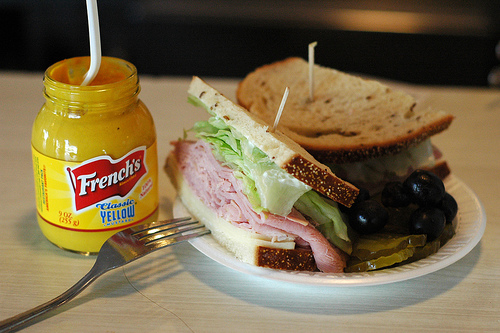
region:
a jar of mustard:
[25, 63, 160, 253]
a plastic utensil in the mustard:
[78, 4, 108, 86]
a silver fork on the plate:
[12, 221, 203, 331]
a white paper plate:
[176, 198, 481, 283]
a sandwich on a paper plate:
[166, 36, 479, 276]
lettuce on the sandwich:
[214, 118, 302, 191]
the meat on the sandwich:
[174, 144, 248, 208]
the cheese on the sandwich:
[195, 200, 220, 222]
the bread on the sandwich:
[248, 51, 442, 149]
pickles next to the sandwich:
[363, 227, 421, 272]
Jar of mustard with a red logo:
[33, 52, 163, 239]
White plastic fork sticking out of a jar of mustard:
[78, 0, 109, 92]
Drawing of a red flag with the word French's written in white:
[59, 140, 153, 211]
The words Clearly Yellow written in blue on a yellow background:
[90, 193, 137, 225]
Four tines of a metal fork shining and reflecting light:
[121, 209, 205, 248]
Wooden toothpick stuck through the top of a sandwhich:
[298, 30, 323, 105]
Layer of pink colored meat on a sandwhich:
[187, 140, 250, 221]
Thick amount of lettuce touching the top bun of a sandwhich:
[208, 128, 300, 203]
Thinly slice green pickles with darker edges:
[352, 230, 424, 263]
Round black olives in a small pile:
[377, 168, 459, 229]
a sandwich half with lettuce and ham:
[178, 75, 353, 285]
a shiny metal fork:
[1, 223, 204, 331]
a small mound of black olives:
[355, 173, 452, 231]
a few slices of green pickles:
[346, 231, 435, 273]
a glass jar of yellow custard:
[32, 57, 163, 253]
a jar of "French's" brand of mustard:
[32, 59, 163, 249]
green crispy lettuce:
[187, 109, 354, 259]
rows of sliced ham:
[166, 132, 332, 259]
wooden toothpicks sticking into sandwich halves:
[262, 39, 322, 126]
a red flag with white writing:
[69, 152, 149, 206]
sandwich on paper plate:
[171, 55, 485, 283]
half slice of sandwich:
[164, 76, 351, 266]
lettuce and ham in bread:
[159, 81, 349, 270]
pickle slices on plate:
[347, 232, 438, 273]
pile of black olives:
[356, 170, 459, 237]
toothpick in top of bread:
[271, 87, 292, 132]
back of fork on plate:
[3, 217, 208, 329]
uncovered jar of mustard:
[33, 57, 160, 257]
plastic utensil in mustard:
[84, 1, 101, 84]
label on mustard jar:
[32, 134, 158, 231]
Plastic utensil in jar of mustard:
[28, 0, 163, 258]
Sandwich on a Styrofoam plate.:
[163, 32, 457, 275]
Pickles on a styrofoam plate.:
[348, 230, 447, 275]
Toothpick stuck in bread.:
[295, 35, 336, 107]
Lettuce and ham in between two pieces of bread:
[161, 70, 358, 275]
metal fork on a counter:
[2, 210, 214, 328]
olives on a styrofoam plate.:
[351, 170, 461, 239]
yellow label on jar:
[30, 138, 163, 235]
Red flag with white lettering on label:
[66, 139, 151, 217]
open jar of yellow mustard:
[28, 51, 161, 256]